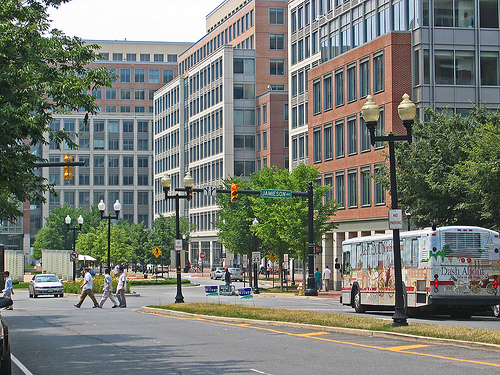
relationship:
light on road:
[223, 178, 243, 206] [3, 275, 225, 374]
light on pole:
[395, 92, 418, 118] [364, 122, 416, 325]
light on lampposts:
[356, 92, 381, 124] [387, 141, 409, 327]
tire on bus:
[351, 282, 361, 307] [335, 226, 497, 308]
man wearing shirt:
[72, 265, 100, 312] [82, 272, 92, 291]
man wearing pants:
[72, 265, 100, 312] [71, 287, 99, 309]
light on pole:
[97, 199, 105, 211] [98, 210, 122, 275]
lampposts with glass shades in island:
[359, 89, 423, 327] [132, 294, 500, 350]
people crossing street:
[116, 266, 127, 308] [5, 287, 457, 373]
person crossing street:
[98, 267, 120, 304] [5, 287, 457, 373]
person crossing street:
[77, 271, 99, 308] [5, 287, 457, 373]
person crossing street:
[2, 272, 18, 308] [5, 287, 457, 373]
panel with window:
[308, 31, 417, 236] [374, 55, 384, 87]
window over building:
[374, 55, 384, 87] [284, 0, 498, 252]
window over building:
[346, 110, 358, 152] [284, 0, 498, 252]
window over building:
[322, 119, 334, 163] [284, 0, 498, 252]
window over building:
[347, 164, 358, 208] [284, 0, 498, 252]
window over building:
[309, 71, 324, 116] [284, 0, 498, 252]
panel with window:
[308, 31, 417, 236] [346, 110, 358, 152]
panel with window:
[308, 31, 417, 236] [322, 119, 334, 163]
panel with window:
[308, 31, 417, 236] [347, 164, 358, 208]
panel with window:
[308, 31, 417, 236] [309, 71, 324, 116]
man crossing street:
[72, 265, 100, 312] [3, 304, 493, 374]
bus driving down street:
[341, 224, 498, 313] [209, 292, 340, 305]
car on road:
[27, 273, 66, 301] [3, 275, 225, 374]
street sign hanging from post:
[259, 185, 296, 203] [260, 187, 296, 196]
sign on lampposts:
[387, 208, 403, 230] [387, 141, 409, 327]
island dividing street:
[157, 297, 497, 342] [5, 298, 497, 373]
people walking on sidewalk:
[30, 234, 312, 326] [312, 287, 343, 297]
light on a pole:
[356, 92, 381, 124] [363, 174, 411, 206]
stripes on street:
[179, 311, 497, 363] [3, 304, 493, 374]